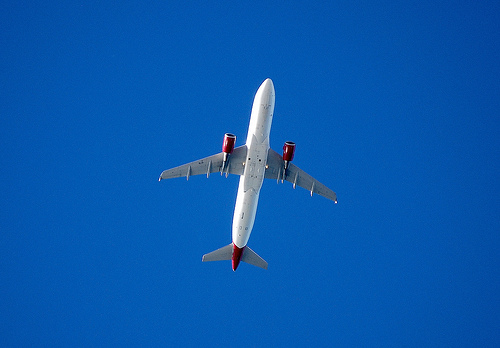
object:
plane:
[156, 77, 340, 274]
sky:
[0, 0, 500, 348]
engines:
[221, 132, 236, 161]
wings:
[157, 144, 247, 183]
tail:
[201, 242, 233, 263]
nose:
[256, 77, 275, 94]